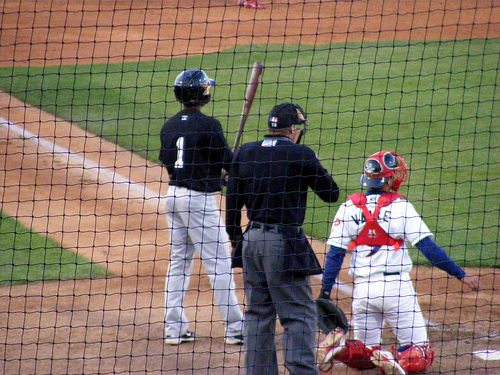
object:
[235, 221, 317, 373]
pants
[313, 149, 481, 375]
catcher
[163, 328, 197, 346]
shoe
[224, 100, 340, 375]
man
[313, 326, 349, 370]
shoes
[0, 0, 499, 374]
baseball court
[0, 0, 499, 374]
netting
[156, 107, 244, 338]
uniform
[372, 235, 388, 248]
red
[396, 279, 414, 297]
white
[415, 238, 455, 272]
blue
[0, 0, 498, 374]
dirt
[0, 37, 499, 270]
grass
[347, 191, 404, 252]
shape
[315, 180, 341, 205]
elbow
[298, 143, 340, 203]
sleeve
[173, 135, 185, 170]
digit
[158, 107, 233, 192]
shirt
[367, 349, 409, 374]
shoes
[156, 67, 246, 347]
batter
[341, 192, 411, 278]
back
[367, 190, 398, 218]
straps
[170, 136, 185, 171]
number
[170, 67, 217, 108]
helmet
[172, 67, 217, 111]
head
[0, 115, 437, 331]
line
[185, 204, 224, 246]
wrinkles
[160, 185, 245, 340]
pants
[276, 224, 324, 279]
pouch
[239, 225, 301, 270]
hip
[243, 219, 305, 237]
belt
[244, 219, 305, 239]
loops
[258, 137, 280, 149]
logo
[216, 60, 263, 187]
baseball bat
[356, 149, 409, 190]
helmet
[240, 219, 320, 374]
pair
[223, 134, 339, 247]
shirt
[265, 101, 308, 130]
cap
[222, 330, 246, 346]
shoe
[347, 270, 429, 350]
pants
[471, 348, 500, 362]
plate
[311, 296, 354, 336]
glove